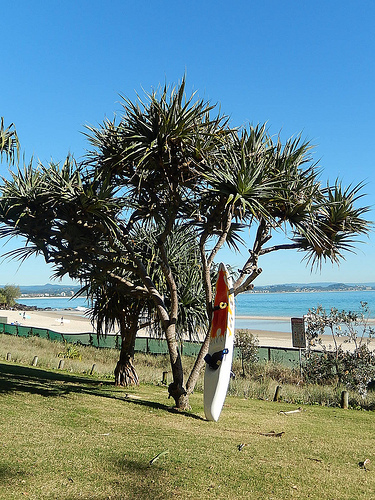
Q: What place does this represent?
A: It represents the field.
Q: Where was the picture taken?
A: It was taken at the field.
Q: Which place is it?
A: It is a field.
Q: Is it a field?
A: Yes, it is a field.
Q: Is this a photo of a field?
A: Yes, it is showing a field.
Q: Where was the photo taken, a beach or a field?
A: It was taken at a field.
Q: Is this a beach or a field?
A: It is a field.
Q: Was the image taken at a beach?
A: No, the picture was taken in a field.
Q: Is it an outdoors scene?
A: Yes, it is outdoors.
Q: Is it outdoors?
A: Yes, it is outdoors.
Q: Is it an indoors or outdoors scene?
A: It is outdoors.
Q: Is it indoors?
A: No, it is outdoors.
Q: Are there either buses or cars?
A: No, there are no cars or buses.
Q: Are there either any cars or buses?
A: No, there are no cars or buses.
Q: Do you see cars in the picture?
A: No, there are no cars.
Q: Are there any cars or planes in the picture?
A: No, there are no cars or planes.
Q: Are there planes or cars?
A: No, there are no cars or planes.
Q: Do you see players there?
A: No, there are no players.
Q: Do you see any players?
A: No, there are no players.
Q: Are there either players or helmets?
A: No, there are no players or helmets.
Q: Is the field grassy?
A: Yes, the field is grassy.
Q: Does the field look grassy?
A: Yes, the field is grassy.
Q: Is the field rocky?
A: No, the field is grassy.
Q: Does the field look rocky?
A: No, the field is grassy.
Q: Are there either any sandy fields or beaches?
A: No, there is a field but it is grassy.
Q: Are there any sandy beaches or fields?
A: No, there is a field but it is grassy.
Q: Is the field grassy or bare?
A: The field is grassy.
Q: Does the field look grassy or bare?
A: The field is grassy.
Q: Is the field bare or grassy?
A: The field is grassy.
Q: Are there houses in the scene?
A: No, there are no houses.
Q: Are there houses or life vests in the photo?
A: No, there are no houses or life vests.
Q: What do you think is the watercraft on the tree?
A: The watercraft is a canoe.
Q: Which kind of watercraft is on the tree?
A: The watercraft is a canoe.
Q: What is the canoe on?
A: The canoe is on the tree.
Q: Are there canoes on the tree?
A: Yes, there is a canoe on the tree.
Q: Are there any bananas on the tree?
A: No, there is a canoe on the tree.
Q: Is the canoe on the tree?
A: Yes, the canoe is on the tree.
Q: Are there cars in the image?
A: No, there are no cars.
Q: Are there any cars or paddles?
A: No, there are no cars or paddles.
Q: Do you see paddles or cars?
A: No, there are no cars or paddles.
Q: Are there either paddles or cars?
A: No, there are no cars or paddles.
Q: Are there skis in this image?
A: No, there are no skis.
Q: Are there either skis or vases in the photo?
A: No, there are no skis or vases.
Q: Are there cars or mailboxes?
A: No, there are no cars or mailboxes.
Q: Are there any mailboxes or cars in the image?
A: No, there are no cars or mailboxes.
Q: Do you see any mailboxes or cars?
A: No, there are no cars or mailboxes.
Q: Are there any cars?
A: No, there are no cars.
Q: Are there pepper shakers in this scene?
A: No, there are no pepper shakers.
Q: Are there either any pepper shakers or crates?
A: No, there are no pepper shakers or crates.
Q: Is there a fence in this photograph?
A: Yes, there is a fence.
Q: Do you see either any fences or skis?
A: Yes, there is a fence.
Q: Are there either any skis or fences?
A: Yes, there is a fence.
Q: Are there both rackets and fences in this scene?
A: No, there is a fence but no rackets.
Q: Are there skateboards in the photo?
A: No, there are no skateboards.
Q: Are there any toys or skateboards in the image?
A: No, there are no skateboards or toys.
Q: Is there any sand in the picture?
A: Yes, there is sand.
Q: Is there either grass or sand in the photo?
A: Yes, there is sand.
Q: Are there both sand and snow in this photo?
A: No, there is sand but no snow.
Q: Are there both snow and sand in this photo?
A: No, there is sand but no snow.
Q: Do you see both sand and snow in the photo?
A: No, there is sand but no snow.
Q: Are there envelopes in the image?
A: No, there are no envelopes.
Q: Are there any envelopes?
A: No, there are no envelopes.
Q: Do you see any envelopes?
A: No, there are no envelopes.